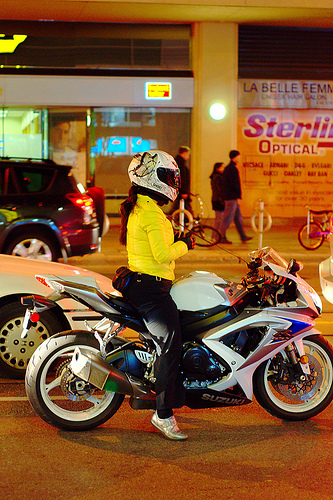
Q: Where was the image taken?
A: It was taken at the street.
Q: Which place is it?
A: It is a street.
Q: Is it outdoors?
A: Yes, it is outdoors.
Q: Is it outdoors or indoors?
A: It is outdoors.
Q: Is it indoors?
A: No, it is outdoors.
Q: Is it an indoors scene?
A: No, it is outdoors.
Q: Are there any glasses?
A: No, there are no glasses.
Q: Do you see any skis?
A: No, there are no skis.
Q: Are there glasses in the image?
A: No, there are no glasses.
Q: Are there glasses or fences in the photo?
A: No, there are no glasses or fences.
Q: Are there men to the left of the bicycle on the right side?
A: Yes, there is a man to the left of the bicycle.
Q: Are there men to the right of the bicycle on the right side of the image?
A: No, the man is to the left of the bicycle.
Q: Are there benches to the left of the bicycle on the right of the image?
A: No, there is a man to the left of the bicycle.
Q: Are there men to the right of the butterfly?
A: Yes, there is a man to the right of the butterfly.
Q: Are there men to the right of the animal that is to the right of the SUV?
A: Yes, there is a man to the right of the butterfly.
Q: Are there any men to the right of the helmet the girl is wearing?
A: Yes, there is a man to the right of the helmet.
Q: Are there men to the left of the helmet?
A: No, the man is to the right of the helmet.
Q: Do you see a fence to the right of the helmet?
A: No, there is a man to the right of the helmet.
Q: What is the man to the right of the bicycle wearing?
A: The man is wearing a jacket.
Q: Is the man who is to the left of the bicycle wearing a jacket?
A: Yes, the man is wearing a jacket.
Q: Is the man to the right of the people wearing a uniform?
A: No, the man is wearing a jacket.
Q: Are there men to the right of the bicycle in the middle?
A: Yes, there is a man to the right of the bicycle.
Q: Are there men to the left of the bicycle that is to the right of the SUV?
A: No, the man is to the right of the bicycle.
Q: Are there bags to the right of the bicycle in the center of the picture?
A: No, there is a man to the right of the bicycle.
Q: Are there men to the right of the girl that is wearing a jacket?
A: Yes, there is a man to the right of the girl.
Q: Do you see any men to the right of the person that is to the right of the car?
A: Yes, there is a man to the right of the girl.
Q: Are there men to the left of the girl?
A: No, the man is to the right of the girl.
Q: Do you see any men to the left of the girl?
A: No, the man is to the right of the girl.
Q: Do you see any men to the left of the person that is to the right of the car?
A: No, the man is to the right of the girl.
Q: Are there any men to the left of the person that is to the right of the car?
A: No, the man is to the right of the girl.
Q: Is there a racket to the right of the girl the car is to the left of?
A: No, there is a man to the right of the girl.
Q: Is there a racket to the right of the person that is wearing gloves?
A: No, there is a man to the right of the girl.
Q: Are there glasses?
A: No, there are no glasses.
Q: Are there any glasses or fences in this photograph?
A: No, there are no glasses or fences.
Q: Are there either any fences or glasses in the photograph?
A: No, there are no glasses or fences.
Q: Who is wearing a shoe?
A: The girl is wearing a shoe.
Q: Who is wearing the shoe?
A: The girl is wearing a shoe.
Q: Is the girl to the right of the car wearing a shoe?
A: Yes, the girl is wearing a shoe.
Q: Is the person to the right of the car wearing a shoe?
A: Yes, the girl is wearing a shoe.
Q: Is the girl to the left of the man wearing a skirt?
A: No, the girl is wearing a shoe.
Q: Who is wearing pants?
A: The girl is wearing pants.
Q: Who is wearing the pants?
A: The girl is wearing pants.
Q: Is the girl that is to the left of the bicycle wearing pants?
A: Yes, the girl is wearing pants.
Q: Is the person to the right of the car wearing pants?
A: Yes, the girl is wearing pants.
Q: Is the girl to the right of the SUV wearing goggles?
A: No, the girl is wearing pants.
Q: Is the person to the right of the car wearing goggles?
A: No, the girl is wearing pants.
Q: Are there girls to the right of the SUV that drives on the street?
A: Yes, there is a girl to the right of the SUV.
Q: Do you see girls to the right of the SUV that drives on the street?
A: Yes, there is a girl to the right of the SUV.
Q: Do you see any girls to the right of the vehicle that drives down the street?
A: Yes, there is a girl to the right of the SUV.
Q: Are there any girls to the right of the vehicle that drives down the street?
A: Yes, there is a girl to the right of the SUV.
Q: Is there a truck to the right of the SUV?
A: No, there is a girl to the right of the SUV.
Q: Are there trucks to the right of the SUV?
A: No, there is a girl to the right of the SUV.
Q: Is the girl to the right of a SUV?
A: Yes, the girl is to the right of a SUV.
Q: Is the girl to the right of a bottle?
A: No, the girl is to the right of a SUV.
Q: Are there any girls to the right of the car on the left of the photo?
A: Yes, there is a girl to the right of the car.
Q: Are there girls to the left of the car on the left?
A: No, the girl is to the right of the car.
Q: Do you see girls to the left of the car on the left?
A: No, the girl is to the right of the car.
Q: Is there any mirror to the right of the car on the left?
A: No, there is a girl to the right of the car.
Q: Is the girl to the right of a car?
A: Yes, the girl is to the right of a car.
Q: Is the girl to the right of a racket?
A: No, the girl is to the right of a car.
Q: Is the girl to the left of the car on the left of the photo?
A: No, the girl is to the right of the car.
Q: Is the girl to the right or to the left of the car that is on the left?
A: The girl is to the right of the car.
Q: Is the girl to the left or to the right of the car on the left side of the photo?
A: The girl is to the right of the car.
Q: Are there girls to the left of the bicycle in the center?
A: Yes, there is a girl to the left of the bicycle.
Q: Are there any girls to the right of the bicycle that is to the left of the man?
A: No, the girl is to the left of the bicycle.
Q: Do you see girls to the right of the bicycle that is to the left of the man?
A: No, the girl is to the left of the bicycle.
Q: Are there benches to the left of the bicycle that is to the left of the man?
A: No, there is a girl to the left of the bicycle.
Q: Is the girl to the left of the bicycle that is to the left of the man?
A: Yes, the girl is to the left of the bicycle.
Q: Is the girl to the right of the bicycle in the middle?
A: No, the girl is to the left of the bicycle.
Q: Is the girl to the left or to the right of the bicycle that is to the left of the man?
A: The girl is to the left of the bicycle.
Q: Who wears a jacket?
A: The girl wears a jacket.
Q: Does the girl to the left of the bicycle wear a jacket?
A: Yes, the girl wears a jacket.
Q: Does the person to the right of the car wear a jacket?
A: Yes, the girl wears a jacket.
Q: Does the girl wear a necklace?
A: No, the girl wears a jacket.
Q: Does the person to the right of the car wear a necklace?
A: No, the girl wears a jacket.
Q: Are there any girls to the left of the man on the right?
A: Yes, there is a girl to the left of the man.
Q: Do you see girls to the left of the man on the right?
A: Yes, there is a girl to the left of the man.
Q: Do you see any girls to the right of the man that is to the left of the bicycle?
A: No, the girl is to the left of the man.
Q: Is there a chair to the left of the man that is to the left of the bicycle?
A: No, there is a girl to the left of the man.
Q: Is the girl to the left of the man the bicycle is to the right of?
A: Yes, the girl is to the left of the man.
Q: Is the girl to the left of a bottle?
A: No, the girl is to the left of the man.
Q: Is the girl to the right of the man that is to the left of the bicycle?
A: No, the girl is to the left of the man.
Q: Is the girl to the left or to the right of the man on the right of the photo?
A: The girl is to the left of the man.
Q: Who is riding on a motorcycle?
A: The girl is riding on a motorcycle.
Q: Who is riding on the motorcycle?
A: The girl is riding on a motorcycle.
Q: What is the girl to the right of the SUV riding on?
A: The girl is riding on a motorcycle.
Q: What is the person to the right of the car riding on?
A: The girl is riding on a motorcycle.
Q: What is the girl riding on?
A: The girl is riding on a motorcycle.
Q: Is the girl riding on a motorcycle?
A: Yes, the girl is riding on a motorcycle.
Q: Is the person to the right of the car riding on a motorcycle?
A: Yes, the girl is riding on a motorcycle.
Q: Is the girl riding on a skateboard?
A: No, the girl is riding on a motorcycle.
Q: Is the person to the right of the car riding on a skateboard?
A: No, the girl is riding on a motorcycle.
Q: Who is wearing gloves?
A: The girl is wearing gloves.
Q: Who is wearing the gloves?
A: The girl is wearing gloves.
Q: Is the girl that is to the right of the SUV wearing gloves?
A: Yes, the girl is wearing gloves.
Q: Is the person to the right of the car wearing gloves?
A: Yes, the girl is wearing gloves.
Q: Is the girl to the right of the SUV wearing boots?
A: No, the girl is wearing gloves.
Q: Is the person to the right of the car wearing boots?
A: No, the girl is wearing gloves.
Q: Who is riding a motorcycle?
A: The girl is riding a motorcycle.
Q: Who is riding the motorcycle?
A: The girl is riding a motorcycle.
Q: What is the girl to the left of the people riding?
A: The girl is riding a motorcycle.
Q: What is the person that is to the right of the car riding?
A: The girl is riding a motorcycle.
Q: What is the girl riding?
A: The girl is riding a motorcycle.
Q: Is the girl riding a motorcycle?
A: Yes, the girl is riding a motorcycle.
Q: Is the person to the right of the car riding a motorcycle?
A: Yes, the girl is riding a motorcycle.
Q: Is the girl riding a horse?
A: No, the girl is riding a motorcycle.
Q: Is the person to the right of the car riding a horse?
A: No, the girl is riding a motorcycle.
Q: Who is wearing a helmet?
A: The girl is wearing a helmet.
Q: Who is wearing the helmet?
A: The girl is wearing a helmet.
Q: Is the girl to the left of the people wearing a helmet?
A: Yes, the girl is wearing a helmet.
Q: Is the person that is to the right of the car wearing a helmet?
A: Yes, the girl is wearing a helmet.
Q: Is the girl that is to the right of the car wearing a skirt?
A: No, the girl is wearing a helmet.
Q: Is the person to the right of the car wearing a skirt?
A: No, the girl is wearing a helmet.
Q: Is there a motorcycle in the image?
A: Yes, there is a motorcycle.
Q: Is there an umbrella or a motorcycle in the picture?
A: Yes, there is a motorcycle.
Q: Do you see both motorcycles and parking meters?
A: No, there is a motorcycle but no parking meters.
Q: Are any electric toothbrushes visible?
A: No, there are no electric toothbrushes.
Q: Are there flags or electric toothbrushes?
A: No, there are no electric toothbrushes or flags.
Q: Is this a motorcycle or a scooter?
A: This is a motorcycle.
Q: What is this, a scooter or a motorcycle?
A: This is a motorcycle.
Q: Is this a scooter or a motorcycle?
A: This is a motorcycle.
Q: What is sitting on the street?
A: The motorbike is sitting on the street.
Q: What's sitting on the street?
A: The motorbike is sitting on the street.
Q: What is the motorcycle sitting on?
A: The motorcycle is sitting on the street.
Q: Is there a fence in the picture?
A: No, there are no fences.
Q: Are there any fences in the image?
A: No, there are no fences.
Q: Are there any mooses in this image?
A: No, there are no mooses.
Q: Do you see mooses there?
A: No, there are no mooses.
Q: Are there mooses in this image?
A: No, there are no mooses.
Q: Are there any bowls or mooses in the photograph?
A: No, there are no mooses or bowls.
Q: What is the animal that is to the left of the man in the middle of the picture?
A: The animal is a butterfly.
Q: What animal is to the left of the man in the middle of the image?
A: The animal is a butterfly.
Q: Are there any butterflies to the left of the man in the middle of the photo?
A: Yes, there is a butterfly to the left of the man.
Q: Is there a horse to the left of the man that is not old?
A: No, there is a butterfly to the left of the man.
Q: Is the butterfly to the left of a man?
A: Yes, the butterfly is to the left of a man.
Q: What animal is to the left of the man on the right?
A: The animal is a butterfly.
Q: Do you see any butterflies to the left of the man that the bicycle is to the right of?
A: Yes, there is a butterfly to the left of the man.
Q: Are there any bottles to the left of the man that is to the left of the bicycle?
A: No, there is a butterfly to the left of the man.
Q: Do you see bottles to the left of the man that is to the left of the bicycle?
A: No, there is a butterfly to the left of the man.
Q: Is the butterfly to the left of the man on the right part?
A: Yes, the butterfly is to the left of the man.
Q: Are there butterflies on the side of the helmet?
A: Yes, there is a butterfly on the side of the helmet.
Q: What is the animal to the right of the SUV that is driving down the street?
A: The animal is a butterfly.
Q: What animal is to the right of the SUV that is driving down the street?
A: The animal is a butterfly.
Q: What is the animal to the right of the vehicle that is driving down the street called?
A: The animal is a butterfly.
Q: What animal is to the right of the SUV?
A: The animal is a butterfly.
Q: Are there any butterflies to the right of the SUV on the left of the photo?
A: Yes, there is a butterfly to the right of the SUV.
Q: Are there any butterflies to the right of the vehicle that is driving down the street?
A: Yes, there is a butterfly to the right of the SUV.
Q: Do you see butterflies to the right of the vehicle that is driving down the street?
A: Yes, there is a butterfly to the right of the SUV.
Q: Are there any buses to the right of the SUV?
A: No, there is a butterfly to the right of the SUV.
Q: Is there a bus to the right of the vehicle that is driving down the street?
A: No, there is a butterfly to the right of the SUV.